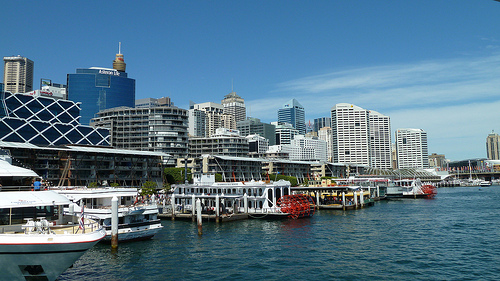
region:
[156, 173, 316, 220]
A river boat with a red wooden propeller.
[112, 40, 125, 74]
The top of a radio tower.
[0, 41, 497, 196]
The skyline of a city, possible Canadian, possibly Vancouver.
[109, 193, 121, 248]
A white wooden spire that sticks out of the water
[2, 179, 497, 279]
An urban harbor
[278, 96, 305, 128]
The top of a tall blue building.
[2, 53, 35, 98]
The top of a tall brown building.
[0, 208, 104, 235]
A front deck on a yacht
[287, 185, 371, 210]
A pier that extends into the harbor.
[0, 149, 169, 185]
A harbor front building.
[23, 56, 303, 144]
buildings built near a river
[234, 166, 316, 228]
a river boat docked near a city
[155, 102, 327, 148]
buildings built in a city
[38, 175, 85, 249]
a yacht anchored near a city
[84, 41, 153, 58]
a tower mounted on top of a building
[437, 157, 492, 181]
flags installed near a river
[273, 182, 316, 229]
a paddlewheel displayed on a riverboat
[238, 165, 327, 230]
a riverboat floating on a river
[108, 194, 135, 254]
post sticking out of the water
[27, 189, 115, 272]
a yacht floating on a river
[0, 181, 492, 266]
water with boats in it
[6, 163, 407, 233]
boats in the water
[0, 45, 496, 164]
buildings behind the boats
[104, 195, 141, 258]
pole in the water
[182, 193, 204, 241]
pole in the water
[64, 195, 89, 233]
flag on the boat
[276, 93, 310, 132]
building with pointed structure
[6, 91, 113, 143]
building with criss cross surface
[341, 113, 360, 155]
windows on the building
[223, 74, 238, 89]
tower on the building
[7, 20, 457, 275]
The boats are sitting at a dock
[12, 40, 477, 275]
The boats are floating on the water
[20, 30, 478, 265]
Their boats are close to the city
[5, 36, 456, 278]
The boats are waiting for passengers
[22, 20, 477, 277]
The boats are sitting in calm water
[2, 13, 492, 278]
The boats are carrying many passengers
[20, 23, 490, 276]
The boats are out in the sunshine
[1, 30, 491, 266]
The boats are all tied up securely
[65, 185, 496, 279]
the water is calm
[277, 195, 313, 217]
the paddles are red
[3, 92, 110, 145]
white x's on the building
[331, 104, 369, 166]
a tall white building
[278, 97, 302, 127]
blue building far away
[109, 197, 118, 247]
pole sticking out of water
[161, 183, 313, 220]
a large white and red boat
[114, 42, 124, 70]
sky scraper in distance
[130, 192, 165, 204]
people on the pier